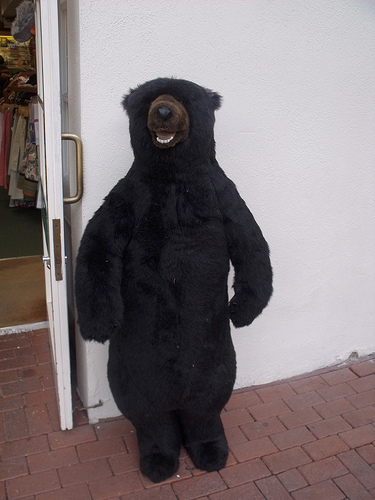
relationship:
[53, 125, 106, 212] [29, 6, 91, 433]
handle on door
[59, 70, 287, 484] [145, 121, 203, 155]
bear has teeth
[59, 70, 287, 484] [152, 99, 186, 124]
bear has nose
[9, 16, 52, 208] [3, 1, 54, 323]
clothes hanging inside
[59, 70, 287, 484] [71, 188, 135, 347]
bear has arm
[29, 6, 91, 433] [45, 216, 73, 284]
door has plate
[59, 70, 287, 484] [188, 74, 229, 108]
bear has ear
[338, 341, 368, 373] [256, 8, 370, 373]
hole in wall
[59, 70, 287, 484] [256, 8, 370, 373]
bear against wall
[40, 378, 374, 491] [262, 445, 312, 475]
sidewalk of tile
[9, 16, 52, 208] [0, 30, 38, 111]
clothes on rack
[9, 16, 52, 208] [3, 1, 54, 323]
clothes in store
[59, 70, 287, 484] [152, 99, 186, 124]
bear with nose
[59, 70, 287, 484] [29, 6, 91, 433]
bear by door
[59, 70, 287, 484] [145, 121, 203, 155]
bear with teeth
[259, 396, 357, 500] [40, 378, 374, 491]
tile on ground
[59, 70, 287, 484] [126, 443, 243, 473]
bear has feet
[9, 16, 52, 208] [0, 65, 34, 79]
clothes on rack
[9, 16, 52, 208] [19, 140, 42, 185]
clothes have flowers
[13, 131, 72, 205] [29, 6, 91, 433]
garment on door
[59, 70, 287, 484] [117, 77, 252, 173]
bear has head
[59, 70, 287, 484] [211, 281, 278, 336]
bear has paws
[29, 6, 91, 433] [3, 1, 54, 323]
door to store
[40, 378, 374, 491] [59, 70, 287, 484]
sidewalk below bear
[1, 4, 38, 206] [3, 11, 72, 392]
items for sale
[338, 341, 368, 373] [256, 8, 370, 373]
crack in wall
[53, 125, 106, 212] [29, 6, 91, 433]
handle of door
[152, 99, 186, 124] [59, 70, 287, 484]
nose of bear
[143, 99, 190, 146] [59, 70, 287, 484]
mouth of bear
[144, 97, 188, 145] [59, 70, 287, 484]
snout of bear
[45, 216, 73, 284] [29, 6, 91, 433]
plate on door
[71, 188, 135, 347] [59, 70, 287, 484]
arm of bear